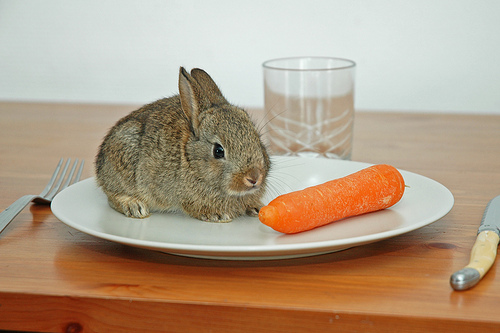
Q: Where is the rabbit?
A: Plate.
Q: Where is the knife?
A: Right of plate.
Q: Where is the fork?
A: Left of the plate.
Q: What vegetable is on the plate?
A: Carrot.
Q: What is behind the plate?
A: Glass.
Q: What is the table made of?
A: Wood.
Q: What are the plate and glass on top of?
A: A table.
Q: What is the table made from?
A: Wood.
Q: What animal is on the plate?
A: A small rabbit.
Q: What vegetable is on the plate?
A: A carrot.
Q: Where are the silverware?
A: On both sides of the plate.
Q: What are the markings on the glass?
A: A decorative design.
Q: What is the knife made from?
A: Stainless steel.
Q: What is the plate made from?
A: Ceramic.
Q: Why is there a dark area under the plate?
A: That is the shadow of the plate.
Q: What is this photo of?
A: A room.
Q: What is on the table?
A: A plate.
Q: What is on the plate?
A: A rabbit.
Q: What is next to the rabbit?
A: A carrot.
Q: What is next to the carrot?
A: A knife.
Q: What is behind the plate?
A: A cup.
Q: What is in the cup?
A: There is nothing.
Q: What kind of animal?
A: Bunny.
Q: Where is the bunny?
A: On the plate.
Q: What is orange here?
A: The carrot.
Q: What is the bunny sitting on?
A: A plate.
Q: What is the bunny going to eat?
A: A carrot.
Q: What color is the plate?
A: White.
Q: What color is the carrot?
A: Orange.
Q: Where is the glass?
A: Behind the plate.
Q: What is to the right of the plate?
A: A knife.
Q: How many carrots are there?
A: One.